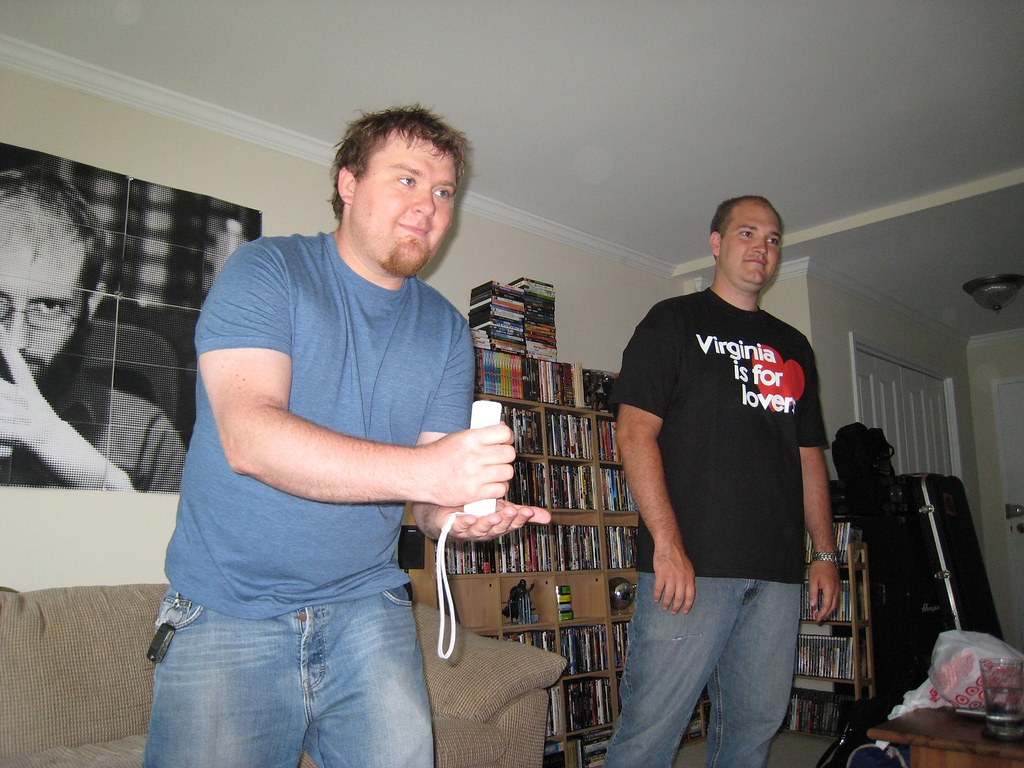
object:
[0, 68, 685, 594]
wall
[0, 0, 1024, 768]
building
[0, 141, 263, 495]
poster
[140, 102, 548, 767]
man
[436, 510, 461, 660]
handle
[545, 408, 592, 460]
media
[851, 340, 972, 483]
door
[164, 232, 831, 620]
shirt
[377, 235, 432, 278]
beard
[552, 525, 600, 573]
movie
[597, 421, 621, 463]
movie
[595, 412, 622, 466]
shelf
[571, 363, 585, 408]
movie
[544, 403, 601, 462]
shelf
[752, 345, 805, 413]
red heart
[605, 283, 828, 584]
man's shirt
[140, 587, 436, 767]
blue jeans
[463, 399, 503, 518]
wii remote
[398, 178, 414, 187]
eye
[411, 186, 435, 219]
nose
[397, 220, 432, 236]
mouth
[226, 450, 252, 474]
elbow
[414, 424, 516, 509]
hand